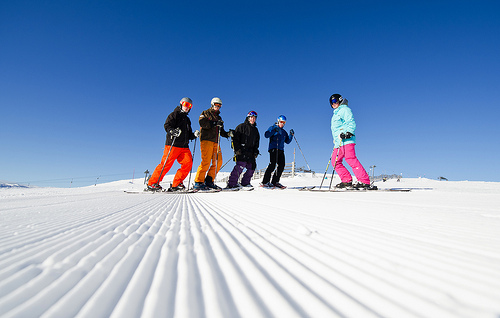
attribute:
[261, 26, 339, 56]
sky — clear, blue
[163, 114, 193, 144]
jacket — black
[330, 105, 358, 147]
snow jacket — baby blue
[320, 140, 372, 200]
snow pants — hot pink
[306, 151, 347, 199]
ski pole — metal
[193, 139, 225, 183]
pants — orange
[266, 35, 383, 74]
sky — deep, blue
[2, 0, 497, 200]
sky — beautiful, clear, blue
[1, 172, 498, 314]
snow — white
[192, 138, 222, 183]
ski pants — orange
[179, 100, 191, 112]
goggles — orange